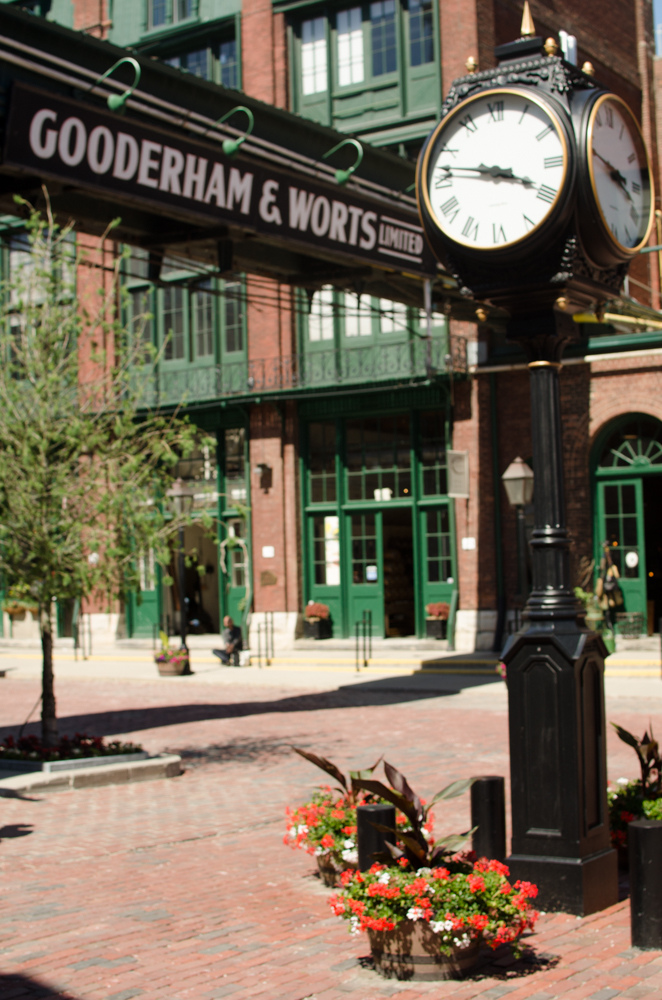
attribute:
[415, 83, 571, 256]
face — white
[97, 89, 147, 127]
light — green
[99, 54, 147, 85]
pole — bent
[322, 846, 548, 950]
flowers — red, white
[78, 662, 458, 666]
edge — yellow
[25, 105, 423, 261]
words — white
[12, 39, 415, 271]
background — black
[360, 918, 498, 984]
pot — round, wooden